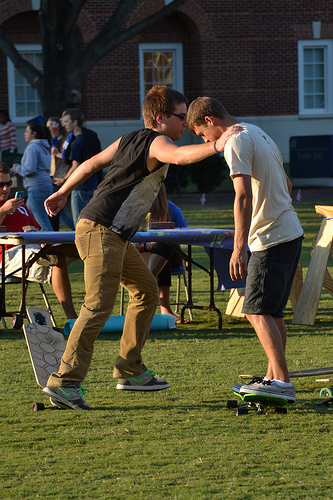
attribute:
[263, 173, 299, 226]
shirt — white, red, blue, black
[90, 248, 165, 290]
pants — brown, part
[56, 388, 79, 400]
logo — green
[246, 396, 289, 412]
skateboard — edge, tipped, gress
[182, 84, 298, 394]
man — falling, playing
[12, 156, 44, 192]
hoodie — gray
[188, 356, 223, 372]
grass — part, green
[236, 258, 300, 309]
shorts — part, black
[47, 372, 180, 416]
shoes — nike, part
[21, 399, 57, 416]
wheel — part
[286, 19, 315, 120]
window — glass, closed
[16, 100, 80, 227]
people — walking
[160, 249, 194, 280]
paint — black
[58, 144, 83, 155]
vest — black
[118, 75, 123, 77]
wall — brown